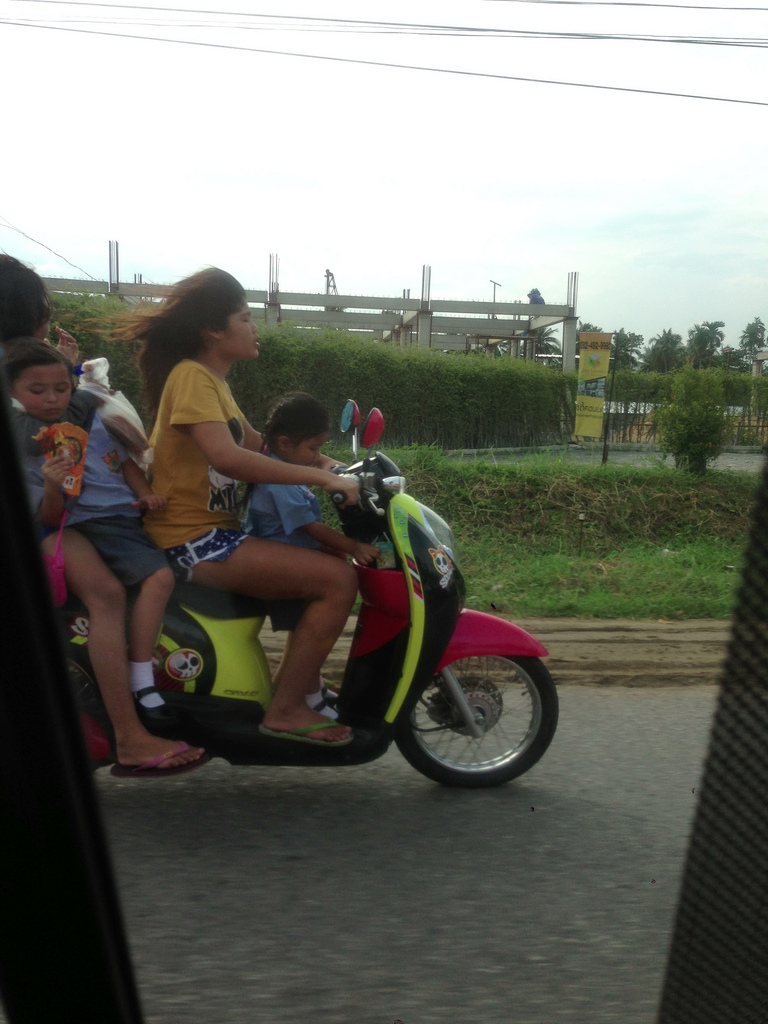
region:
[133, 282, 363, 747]
a woman driving a scooter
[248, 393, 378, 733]
a little girl sitting on a scooter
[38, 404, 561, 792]
a pink and green scooter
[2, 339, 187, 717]
a little girl on a scooter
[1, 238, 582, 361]
a building under construction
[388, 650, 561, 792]
a wheel on a scooter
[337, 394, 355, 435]
a mirror on a scooter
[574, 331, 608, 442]
a sign on a pole near a construction site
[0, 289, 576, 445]
bushes near a construction site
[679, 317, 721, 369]
a distant palm tree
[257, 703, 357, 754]
green sandal on right foot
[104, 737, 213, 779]
pink sandal on foot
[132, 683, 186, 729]
black shoe on foot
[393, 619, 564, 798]
front tire on bike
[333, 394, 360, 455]
mirror on the bike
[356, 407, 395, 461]
mirror on the bike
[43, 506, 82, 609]
pink bag on girl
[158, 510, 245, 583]
blue shorts on girl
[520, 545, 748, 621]
green grass on ground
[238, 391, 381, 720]
girl wearing a blue shirt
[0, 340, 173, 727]
girl wearing a blue shirt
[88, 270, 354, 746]
woman wearing an orange shirt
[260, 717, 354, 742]
a green flip flop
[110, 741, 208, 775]
a pink flip flop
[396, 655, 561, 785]
a black rubber tire with wire spokes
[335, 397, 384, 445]
a pair of rear view mirrors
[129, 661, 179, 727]
black dress shoe with white sock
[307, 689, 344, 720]
black dress shoe with white sock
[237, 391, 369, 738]
little girl standing on scooter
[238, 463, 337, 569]
little girl wearing blue shirt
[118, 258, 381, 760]
lady driving a scooter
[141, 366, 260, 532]
lady wearing yellow shirt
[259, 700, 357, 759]
lady wearing flip flops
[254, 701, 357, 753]
lady's flip flops are green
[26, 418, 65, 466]
girl holding cake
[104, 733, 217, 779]
woman wearing flip flops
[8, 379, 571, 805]
scooter on road is pink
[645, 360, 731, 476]
small bush behind road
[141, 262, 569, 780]
girl in yellow shirt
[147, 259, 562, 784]
girl in yellow shirt driving scooter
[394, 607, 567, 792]
red fender on front of scooter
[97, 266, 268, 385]
girls hair blowing in the wind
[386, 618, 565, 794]
black tire on front of scooter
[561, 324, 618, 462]
yellow banner on black pole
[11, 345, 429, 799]
girl riding on scooter eating chips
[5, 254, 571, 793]
four people riding on small scooter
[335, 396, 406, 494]
red mirrors on front of scooter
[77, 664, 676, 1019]
The black paved road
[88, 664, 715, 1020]
A black paved road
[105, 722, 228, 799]
The pink flip flop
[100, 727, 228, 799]
A pink flip flop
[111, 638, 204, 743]
The child's black shoe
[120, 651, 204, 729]
A child's black shoe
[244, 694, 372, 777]
The green flip flop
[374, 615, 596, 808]
The front tire of the scooter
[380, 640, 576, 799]
A front tire of the scooter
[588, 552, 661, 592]
the grass is green and high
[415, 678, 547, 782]
front tire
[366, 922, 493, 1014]
the ground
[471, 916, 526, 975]
the street is grey